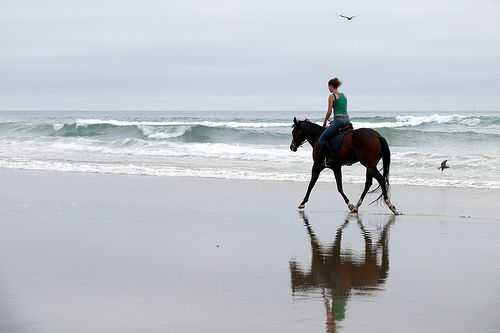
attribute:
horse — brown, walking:
[274, 117, 394, 187]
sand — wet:
[219, 193, 308, 235]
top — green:
[331, 90, 351, 115]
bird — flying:
[333, 6, 359, 27]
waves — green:
[110, 121, 245, 148]